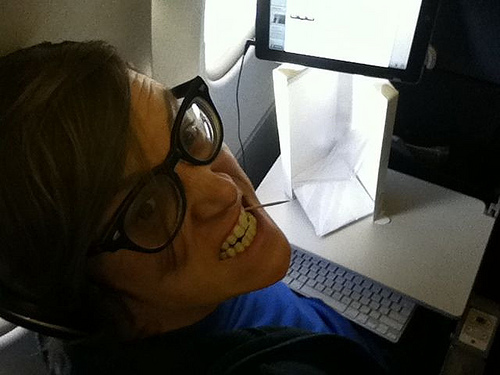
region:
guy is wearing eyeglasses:
[18, 32, 286, 290]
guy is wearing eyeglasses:
[76, 45, 237, 253]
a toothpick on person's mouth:
[215, 160, 300, 249]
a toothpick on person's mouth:
[209, 178, 289, 286]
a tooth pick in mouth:
[237, 188, 312, 225]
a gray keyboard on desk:
[253, 236, 455, 361]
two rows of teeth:
[212, 215, 317, 295]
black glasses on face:
[95, 72, 237, 269]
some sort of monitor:
[248, 2, 421, 92]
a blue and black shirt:
[186, 290, 405, 372]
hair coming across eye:
[99, 116, 219, 313]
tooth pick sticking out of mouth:
[229, 188, 286, 225]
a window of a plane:
[197, 1, 258, 90]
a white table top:
[258, 144, 498, 301]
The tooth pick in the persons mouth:
[253, 196, 303, 207]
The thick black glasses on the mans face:
[86, 75, 223, 247]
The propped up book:
[276, 59, 384, 221]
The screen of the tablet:
[256, 1, 426, 86]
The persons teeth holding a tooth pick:
[229, 206, 253, 266]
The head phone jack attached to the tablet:
[243, 35, 257, 59]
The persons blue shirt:
[119, 298, 416, 373]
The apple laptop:
[226, 141, 496, 343]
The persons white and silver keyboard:
[280, 245, 445, 350]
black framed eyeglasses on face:
[77, 73, 224, 257]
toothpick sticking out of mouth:
[243, 198, 290, 212]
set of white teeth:
[219, 205, 261, 257]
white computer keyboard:
[275, 243, 420, 348]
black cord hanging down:
[235, 38, 252, 175]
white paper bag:
[270, 61, 397, 236]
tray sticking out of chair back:
[251, 141, 498, 323]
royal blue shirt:
[188, 280, 383, 354]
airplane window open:
[202, 1, 256, 76]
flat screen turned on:
[252, 0, 437, 82]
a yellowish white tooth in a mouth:
[220, 241, 224, 250]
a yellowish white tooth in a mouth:
[225, 232, 235, 245]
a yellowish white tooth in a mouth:
[233, 224, 242, 237]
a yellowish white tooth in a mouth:
[237, 213, 248, 225]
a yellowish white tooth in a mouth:
[240, 208, 247, 214]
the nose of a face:
[182, 163, 239, 220]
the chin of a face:
[239, 220, 296, 291]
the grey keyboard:
[275, 239, 413, 341]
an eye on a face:
[180, 119, 200, 144]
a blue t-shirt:
[207, 276, 356, 346]